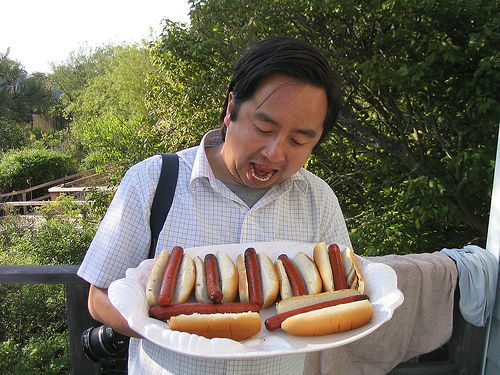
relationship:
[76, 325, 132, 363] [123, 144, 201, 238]
camera strapped over shoulder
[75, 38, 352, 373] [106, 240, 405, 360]
guy holding plate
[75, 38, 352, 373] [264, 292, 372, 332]
guy has hot dog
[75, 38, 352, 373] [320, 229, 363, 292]
guy will eat hotdog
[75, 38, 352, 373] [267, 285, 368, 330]
guy will eat hotdog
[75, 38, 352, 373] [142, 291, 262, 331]
guy will eat hotdog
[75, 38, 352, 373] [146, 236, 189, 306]
guy will eat hotdog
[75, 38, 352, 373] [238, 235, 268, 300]
guy will eat hotdog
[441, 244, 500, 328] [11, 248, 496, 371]
clothing hanging off balcony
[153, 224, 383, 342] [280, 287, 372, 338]
hot dog in bun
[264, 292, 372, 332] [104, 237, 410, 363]
hot dog on plate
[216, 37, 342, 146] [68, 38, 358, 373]
black hair on guy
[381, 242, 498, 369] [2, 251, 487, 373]
clothing on balcony rail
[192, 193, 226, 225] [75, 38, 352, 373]
shirt on guy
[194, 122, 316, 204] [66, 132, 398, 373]
collar on shirt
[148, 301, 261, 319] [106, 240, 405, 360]
hot dog on plate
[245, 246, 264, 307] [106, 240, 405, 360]
hot dog on plate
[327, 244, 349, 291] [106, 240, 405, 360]
hot dog on plate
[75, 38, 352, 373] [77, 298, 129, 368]
guy carrying camera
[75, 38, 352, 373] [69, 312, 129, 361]
guy carrying camera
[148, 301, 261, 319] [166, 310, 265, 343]
hot dog on bun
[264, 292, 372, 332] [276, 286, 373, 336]
hot dog on bun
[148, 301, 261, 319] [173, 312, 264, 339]
hot dog on bun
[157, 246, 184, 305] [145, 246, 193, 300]
hot dog on bun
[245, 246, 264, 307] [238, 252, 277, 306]
hot dog on bun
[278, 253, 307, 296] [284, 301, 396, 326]
hot dog on bun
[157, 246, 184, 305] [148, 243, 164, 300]
hot dog on bun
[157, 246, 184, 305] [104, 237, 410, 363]
hot dog on plate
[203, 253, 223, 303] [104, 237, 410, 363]
hot dog on plate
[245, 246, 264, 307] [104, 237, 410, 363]
hot dog on plate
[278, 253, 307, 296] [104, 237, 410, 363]
hot dog on plate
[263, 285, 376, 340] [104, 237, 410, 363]
hot dog on plate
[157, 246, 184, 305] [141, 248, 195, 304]
hot dog on bun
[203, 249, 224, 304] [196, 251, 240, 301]
hot dog on bun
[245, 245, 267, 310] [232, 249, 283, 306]
hot dog on bun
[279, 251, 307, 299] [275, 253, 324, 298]
hot dog on bun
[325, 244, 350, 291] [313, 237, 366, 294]
hot dog on bun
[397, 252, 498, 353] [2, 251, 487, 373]
clothing hanging over balcony rail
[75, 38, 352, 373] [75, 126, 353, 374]
guy wearing shirt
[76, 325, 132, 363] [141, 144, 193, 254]
camera hanging from shoulder